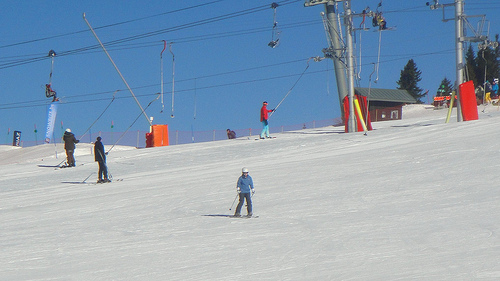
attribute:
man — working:
[244, 86, 283, 159]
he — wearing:
[247, 96, 286, 155]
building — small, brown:
[329, 59, 420, 146]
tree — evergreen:
[392, 52, 429, 104]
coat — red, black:
[253, 99, 279, 130]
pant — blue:
[248, 120, 271, 151]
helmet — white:
[242, 163, 253, 178]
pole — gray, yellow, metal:
[442, 19, 484, 120]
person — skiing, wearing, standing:
[199, 154, 273, 252]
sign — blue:
[491, 80, 499, 93]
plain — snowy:
[99, 183, 183, 265]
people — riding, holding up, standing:
[347, 12, 394, 42]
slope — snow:
[134, 142, 198, 274]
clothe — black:
[91, 140, 117, 176]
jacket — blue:
[231, 172, 260, 203]